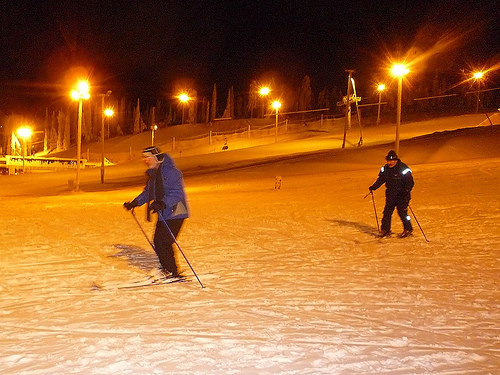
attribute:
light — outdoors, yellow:
[65, 81, 92, 103]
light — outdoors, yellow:
[176, 91, 189, 104]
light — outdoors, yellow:
[384, 57, 409, 81]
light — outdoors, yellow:
[258, 88, 282, 111]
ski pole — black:
[368, 193, 380, 236]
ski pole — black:
[408, 205, 435, 245]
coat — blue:
[134, 162, 189, 220]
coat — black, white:
[374, 163, 415, 201]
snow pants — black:
[154, 223, 186, 278]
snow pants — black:
[380, 197, 412, 232]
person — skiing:
[137, 145, 190, 281]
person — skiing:
[371, 151, 414, 236]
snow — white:
[86, 281, 495, 351]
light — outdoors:
[18, 126, 31, 140]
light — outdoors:
[473, 73, 482, 82]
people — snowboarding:
[137, 146, 436, 281]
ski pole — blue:
[156, 216, 208, 288]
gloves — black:
[126, 196, 165, 212]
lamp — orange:
[71, 84, 89, 99]